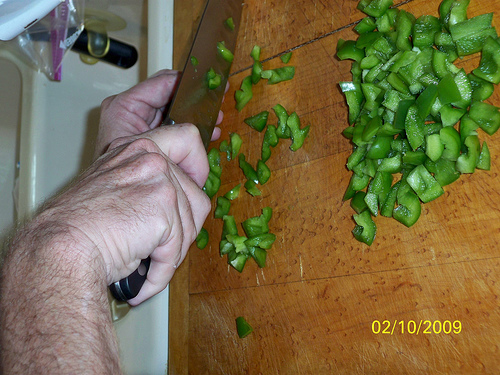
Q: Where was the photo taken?
A: A kitchen.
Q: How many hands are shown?
A: One.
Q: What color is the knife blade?
A: Silver.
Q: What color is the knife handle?
A: Black.